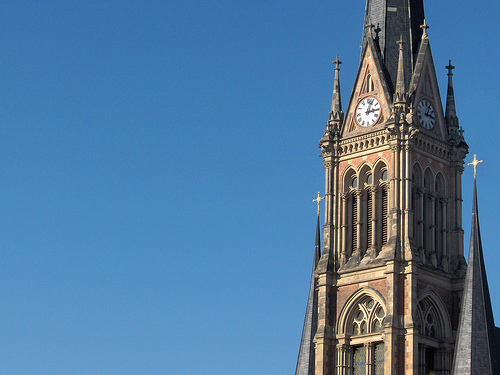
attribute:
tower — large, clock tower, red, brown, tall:
[294, 2, 496, 374]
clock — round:
[354, 95, 383, 128]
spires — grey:
[317, 15, 467, 147]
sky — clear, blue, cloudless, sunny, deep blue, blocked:
[3, 1, 500, 374]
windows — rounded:
[337, 163, 449, 374]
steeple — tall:
[352, 0, 435, 41]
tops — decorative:
[320, 2, 466, 162]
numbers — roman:
[354, 96, 381, 127]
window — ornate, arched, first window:
[337, 288, 386, 375]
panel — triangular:
[341, 37, 395, 139]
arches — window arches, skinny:
[343, 159, 390, 193]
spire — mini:
[391, 33, 410, 99]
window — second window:
[412, 285, 452, 374]